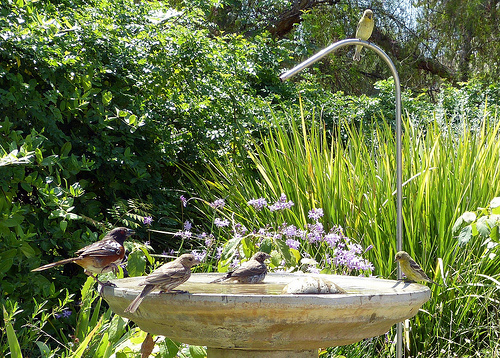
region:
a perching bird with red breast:
[28, 222, 134, 296]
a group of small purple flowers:
[177, 185, 374, 276]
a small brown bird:
[219, 248, 274, 283]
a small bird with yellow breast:
[392, 248, 440, 288]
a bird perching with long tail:
[123, 245, 203, 314]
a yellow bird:
[352, 5, 374, 66]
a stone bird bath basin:
[94, 270, 433, 356]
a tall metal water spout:
[276, 35, 410, 356]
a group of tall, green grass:
[167, 93, 498, 278]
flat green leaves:
[449, 190, 497, 265]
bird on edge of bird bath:
[61, 233, 128, 284]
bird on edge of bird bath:
[138, 248, 199, 310]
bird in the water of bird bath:
[219, 240, 280, 285]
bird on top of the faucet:
[338, 7, 385, 58]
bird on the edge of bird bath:
[384, 245, 430, 287]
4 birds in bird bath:
[58, 220, 453, 356]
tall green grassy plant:
[255, 123, 487, 223]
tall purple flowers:
[177, 192, 384, 253]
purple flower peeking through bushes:
[53, 300, 78, 324]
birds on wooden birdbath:
[81, 206, 351, 309]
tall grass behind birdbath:
[290, 125, 497, 260]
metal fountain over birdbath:
[295, 40, 427, 255]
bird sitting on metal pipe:
[345, 11, 402, 58]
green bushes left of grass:
[0, 15, 230, 281]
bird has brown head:
[92, 212, 132, 248]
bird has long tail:
[32, 250, 127, 275]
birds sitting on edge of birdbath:
[60, 225, 275, 310]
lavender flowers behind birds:
[152, 165, 414, 304]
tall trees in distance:
[245, 8, 499, 123]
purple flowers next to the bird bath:
[266, 189, 354, 275]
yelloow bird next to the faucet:
[391, 243, 423, 283]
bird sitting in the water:
[231, 251, 272, 286]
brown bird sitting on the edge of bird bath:
[138, 254, 206, 310]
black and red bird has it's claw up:
[83, 215, 128, 277]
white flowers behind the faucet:
[471, 195, 498, 262]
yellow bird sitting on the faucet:
[347, 4, 380, 73]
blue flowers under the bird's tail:
[49, 300, 93, 317]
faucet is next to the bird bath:
[386, 192, 431, 308]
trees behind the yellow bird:
[388, 11, 430, 100]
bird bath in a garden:
[100, 270, 425, 356]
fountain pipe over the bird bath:
[277, 35, 402, 355]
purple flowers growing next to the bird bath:
[165, 187, 370, 272]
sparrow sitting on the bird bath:
[32, 226, 127, 276]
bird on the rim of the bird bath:
[125, 250, 196, 310]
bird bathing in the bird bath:
[210, 250, 265, 280]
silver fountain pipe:
[280, 35, 400, 355]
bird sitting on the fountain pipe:
[352, 6, 372, 61]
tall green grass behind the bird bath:
[210, 101, 495, 354]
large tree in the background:
[298, 0, 495, 86]